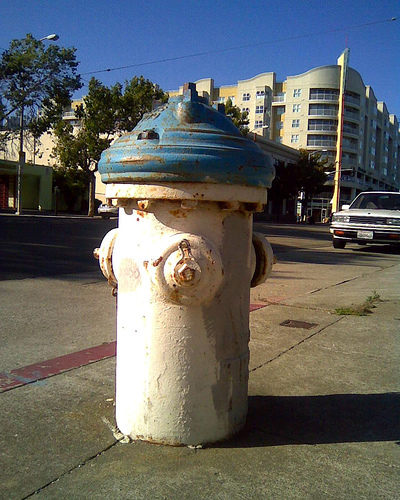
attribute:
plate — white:
[353, 229, 377, 241]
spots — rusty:
[151, 254, 164, 267]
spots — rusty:
[142, 258, 148, 271]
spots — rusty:
[210, 258, 216, 266]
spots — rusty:
[208, 246, 213, 254]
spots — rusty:
[134, 216, 142, 224]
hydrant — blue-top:
[89, 79, 278, 449]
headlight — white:
[388, 217, 399, 223]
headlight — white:
[333, 215, 349, 221]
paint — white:
[94, 429, 172, 477]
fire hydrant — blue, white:
[93, 81, 277, 445]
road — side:
[275, 230, 348, 285]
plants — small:
[313, 241, 390, 365]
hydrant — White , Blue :
[36, 63, 320, 496]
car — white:
[312, 175, 398, 263]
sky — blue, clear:
[7, 7, 399, 77]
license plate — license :
[356, 228, 373, 240]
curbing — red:
[326, 80, 350, 232]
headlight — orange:
[314, 222, 382, 252]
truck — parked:
[312, 112, 375, 267]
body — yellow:
[47, 106, 297, 420]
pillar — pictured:
[330, 189, 338, 201]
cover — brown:
[280, 317, 317, 326]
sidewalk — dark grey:
[0, 250, 398, 434]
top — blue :
[92, 86, 279, 191]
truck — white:
[328, 188, 397, 245]